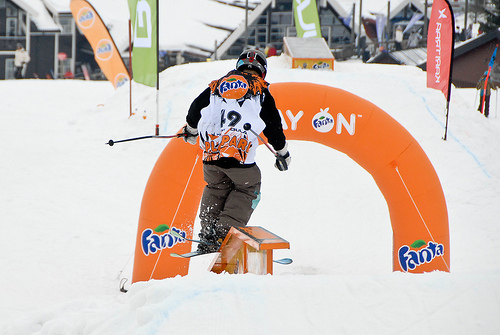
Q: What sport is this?
A: Skiing.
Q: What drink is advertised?
A: Fanta.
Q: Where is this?
A: Ski slopes.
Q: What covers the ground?
A: Snow.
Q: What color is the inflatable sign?
A: Orange.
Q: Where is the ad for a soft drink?
A: On the Fanta display.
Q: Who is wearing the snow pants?
A: Skier.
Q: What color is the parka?
A: Black, white and orange.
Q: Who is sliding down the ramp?
A: The snowboarder.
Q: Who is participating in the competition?
A: The snowboarder.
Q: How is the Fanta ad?
A: Inflated.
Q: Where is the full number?
A: Hidden in fold.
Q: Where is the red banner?
A: Stuck in snow.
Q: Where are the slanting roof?
A: On the chalet.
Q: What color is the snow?
A: White.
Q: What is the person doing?
A: Skiing.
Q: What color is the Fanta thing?
A: Orange.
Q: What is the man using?
A: Skis.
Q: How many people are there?
A: One.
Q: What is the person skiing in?
A: A challenge.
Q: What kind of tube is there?
A: A blow up tube.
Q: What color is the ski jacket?
A: Black, white, orange and blue.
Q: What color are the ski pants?
A: Gray.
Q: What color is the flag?
A: Red and white.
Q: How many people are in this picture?
A: One.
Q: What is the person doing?
A: Skiing.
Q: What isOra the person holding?
A: Ski poles.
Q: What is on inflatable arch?
A: Fanta.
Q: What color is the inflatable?
A: Orange.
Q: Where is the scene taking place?
A: Ski resort.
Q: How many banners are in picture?
A: 4.